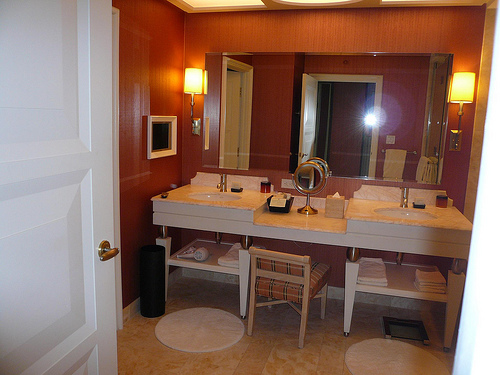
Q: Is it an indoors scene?
A: Yes, it is indoors.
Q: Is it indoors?
A: Yes, it is indoors.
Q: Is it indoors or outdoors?
A: It is indoors.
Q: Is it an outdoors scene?
A: No, it is indoors.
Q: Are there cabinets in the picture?
A: No, there are no cabinets.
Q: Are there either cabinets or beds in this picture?
A: No, there are no cabinets or beds.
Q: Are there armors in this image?
A: No, there are no armors.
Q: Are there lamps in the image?
A: Yes, there is a lamp.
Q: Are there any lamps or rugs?
A: Yes, there is a lamp.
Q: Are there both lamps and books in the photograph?
A: No, there is a lamp but no books.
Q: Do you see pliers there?
A: No, there are no pliers.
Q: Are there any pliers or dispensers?
A: No, there are no pliers or dispensers.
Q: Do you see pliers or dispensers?
A: No, there are no pliers or dispensers.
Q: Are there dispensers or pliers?
A: No, there are no pliers or dispensers.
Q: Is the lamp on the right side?
A: Yes, the lamp is on the right of the image.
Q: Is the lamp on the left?
A: No, the lamp is on the right of the image.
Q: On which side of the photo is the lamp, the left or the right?
A: The lamp is on the right of the image.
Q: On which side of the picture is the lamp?
A: The lamp is on the right of the image.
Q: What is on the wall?
A: The lamp is on the wall.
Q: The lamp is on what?
A: The lamp is on the wall.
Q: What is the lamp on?
A: The lamp is on the wall.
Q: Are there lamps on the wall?
A: Yes, there is a lamp on the wall.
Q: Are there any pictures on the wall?
A: No, there is a lamp on the wall.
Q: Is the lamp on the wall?
A: Yes, the lamp is on the wall.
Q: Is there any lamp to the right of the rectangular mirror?
A: Yes, there is a lamp to the right of the mirror.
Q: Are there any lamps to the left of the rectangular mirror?
A: No, the lamp is to the right of the mirror.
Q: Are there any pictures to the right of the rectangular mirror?
A: No, there is a lamp to the right of the mirror.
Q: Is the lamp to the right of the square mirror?
A: Yes, the lamp is to the right of the mirror.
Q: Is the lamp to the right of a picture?
A: No, the lamp is to the right of the mirror.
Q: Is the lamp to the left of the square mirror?
A: No, the lamp is to the right of the mirror.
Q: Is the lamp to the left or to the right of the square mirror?
A: The lamp is to the right of the mirror.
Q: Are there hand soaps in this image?
A: No, there are no hand soaps.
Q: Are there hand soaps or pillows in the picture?
A: No, there are no hand soaps or pillows.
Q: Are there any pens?
A: No, there are no pens.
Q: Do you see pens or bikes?
A: No, there are no pens or bikes.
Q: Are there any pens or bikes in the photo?
A: No, there are no pens or bikes.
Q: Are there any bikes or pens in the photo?
A: No, there are no pens or bikes.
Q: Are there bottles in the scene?
A: No, there are no bottles.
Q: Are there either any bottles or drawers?
A: No, there are no bottles or drawers.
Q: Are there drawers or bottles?
A: No, there are no bottles or drawers.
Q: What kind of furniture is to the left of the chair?
A: The piece of furniture is a shelf.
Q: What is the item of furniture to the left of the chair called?
A: The piece of furniture is a shelf.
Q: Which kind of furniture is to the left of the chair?
A: The piece of furniture is a shelf.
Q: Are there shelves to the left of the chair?
A: Yes, there is a shelf to the left of the chair.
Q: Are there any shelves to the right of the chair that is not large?
A: No, the shelf is to the left of the chair.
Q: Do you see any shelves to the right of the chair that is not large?
A: No, the shelf is to the left of the chair.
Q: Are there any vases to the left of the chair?
A: No, there is a shelf to the left of the chair.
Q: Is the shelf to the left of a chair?
A: Yes, the shelf is to the left of a chair.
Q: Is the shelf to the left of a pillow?
A: No, the shelf is to the left of a chair.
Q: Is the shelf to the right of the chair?
A: No, the shelf is to the left of the chair.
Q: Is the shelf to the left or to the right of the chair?
A: The shelf is to the left of the chair.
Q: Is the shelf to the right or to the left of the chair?
A: The shelf is to the left of the chair.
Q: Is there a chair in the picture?
A: Yes, there is a chair.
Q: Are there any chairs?
A: Yes, there is a chair.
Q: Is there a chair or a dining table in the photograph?
A: Yes, there is a chair.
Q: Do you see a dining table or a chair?
A: Yes, there is a chair.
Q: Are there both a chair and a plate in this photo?
A: No, there is a chair but no plates.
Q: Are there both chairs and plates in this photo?
A: No, there is a chair but no plates.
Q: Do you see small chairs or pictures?
A: Yes, there is a small chair.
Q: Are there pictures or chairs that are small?
A: Yes, the chair is small.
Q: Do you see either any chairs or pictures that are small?
A: Yes, the chair is small.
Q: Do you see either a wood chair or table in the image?
A: Yes, there is a wood chair.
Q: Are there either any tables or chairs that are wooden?
A: Yes, the chair is wooden.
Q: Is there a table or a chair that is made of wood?
A: Yes, the chair is made of wood.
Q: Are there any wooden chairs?
A: Yes, there is a wood chair.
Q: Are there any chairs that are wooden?
A: Yes, there is a chair that is wooden.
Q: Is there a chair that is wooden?
A: Yes, there is a chair that is wooden.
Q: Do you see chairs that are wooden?
A: Yes, there is a chair that is wooden.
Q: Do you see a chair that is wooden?
A: Yes, there is a chair that is wooden.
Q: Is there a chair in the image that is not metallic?
A: Yes, there is a wooden chair.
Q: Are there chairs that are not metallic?
A: Yes, there is a wooden chair.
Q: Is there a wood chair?
A: Yes, there is a chair that is made of wood.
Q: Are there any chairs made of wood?
A: Yes, there is a chair that is made of wood.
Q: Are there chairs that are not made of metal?
A: Yes, there is a chair that is made of wood.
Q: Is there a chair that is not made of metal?
A: Yes, there is a chair that is made of wood.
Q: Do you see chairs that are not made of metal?
A: Yes, there is a chair that is made of wood.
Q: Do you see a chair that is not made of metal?
A: Yes, there is a chair that is made of wood.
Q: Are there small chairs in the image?
A: Yes, there is a small chair.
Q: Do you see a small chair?
A: Yes, there is a small chair.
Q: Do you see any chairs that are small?
A: Yes, there is a chair that is small.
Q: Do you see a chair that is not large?
A: Yes, there is a small chair.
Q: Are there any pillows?
A: No, there are no pillows.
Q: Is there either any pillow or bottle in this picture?
A: No, there are no pillows or bottles.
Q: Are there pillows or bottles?
A: No, there are no pillows or bottles.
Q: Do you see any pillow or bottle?
A: No, there are no pillows or bottles.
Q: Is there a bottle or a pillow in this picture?
A: No, there are no pillows or bottles.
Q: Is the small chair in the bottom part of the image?
A: Yes, the chair is in the bottom of the image.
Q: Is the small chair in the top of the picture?
A: No, the chair is in the bottom of the image.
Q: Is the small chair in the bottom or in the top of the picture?
A: The chair is in the bottom of the image.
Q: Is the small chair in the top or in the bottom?
A: The chair is in the bottom of the image.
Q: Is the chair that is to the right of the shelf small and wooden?
A: Yes, the chair is small and wooden.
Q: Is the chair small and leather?
A: No, the chair is small but wooden.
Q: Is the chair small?
A: Yes, the chair is small.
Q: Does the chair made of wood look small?
A: Yes, the chair is small.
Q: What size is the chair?
A: The chair is small.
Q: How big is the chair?
A: The chair is small.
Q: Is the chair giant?
A: No, the chair is small.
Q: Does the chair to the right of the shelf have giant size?
A: No, the chair is small.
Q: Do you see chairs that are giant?
A: No, there is a chair but it is small.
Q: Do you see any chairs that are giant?
A: No, there is a chair but it is small.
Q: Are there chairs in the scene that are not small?
A: No, there is a chair but it is small.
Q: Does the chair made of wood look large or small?
A: The chair is small.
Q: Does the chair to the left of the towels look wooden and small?
A: Yes, the chair is wooden and small.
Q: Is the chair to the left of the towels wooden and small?
A: Yes, the chair is wooden and small.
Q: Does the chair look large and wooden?
A: No, the chair is wooden but small.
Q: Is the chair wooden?
A: Yes, the chair is wooden.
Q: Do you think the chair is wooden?
A: Yes, the chair is wooden.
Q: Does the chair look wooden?
A: Yes, the chair is wooden.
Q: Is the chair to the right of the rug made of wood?
A: Yes, the chair is made of wood.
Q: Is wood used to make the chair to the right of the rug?
A: Yes, the chair is made of wood.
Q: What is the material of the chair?
A: The chair is made of wood.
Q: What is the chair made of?
A: The chair is made of wood.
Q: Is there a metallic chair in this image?
A: No, there is a chair but it is wooden.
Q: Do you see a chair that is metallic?
A: No, there is a chair but it is wooden.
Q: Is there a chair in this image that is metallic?
A: No, there is a chair but it is wooden.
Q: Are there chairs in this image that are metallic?
A: No, there is a chair but it is wooden.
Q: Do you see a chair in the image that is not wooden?
A: No, there is a chair but it is wooden.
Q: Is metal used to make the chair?
A: No, the chair is made of wood.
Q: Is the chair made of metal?
A: No, the chair is made of wood.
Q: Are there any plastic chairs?
A: No, there is a chair but it is made of wood.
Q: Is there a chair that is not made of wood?
A: No, there is a chair but it is made of wood.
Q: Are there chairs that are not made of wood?
A: No, there is a chair but it is made of wood.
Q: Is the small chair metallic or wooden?
A: The chair is wooden.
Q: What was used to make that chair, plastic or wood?
A: The chair is made of wood.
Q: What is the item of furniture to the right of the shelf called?
A: The piece of furniture is a chair.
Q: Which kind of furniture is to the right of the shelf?
A: The piece of furniture is a chair.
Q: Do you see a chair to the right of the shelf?
A: Yes, there is a chair to the right of the shelf.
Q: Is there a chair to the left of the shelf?
A: No, the chair is to the right of the shelf.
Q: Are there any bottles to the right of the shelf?
A: No, there is a chair to the right of the shelf.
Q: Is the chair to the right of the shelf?
A: Yes, the chair is to the right of the shelf.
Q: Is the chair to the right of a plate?
A: No, the chair is to the right of the shelf.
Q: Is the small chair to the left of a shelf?
A: No, the chair is to the right of a shelf.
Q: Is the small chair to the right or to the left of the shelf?
A: The chair is to the right of the shelf.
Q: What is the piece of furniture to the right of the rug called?
A: The piece of furniture is a chair.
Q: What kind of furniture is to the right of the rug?
A: The piece of furniture is a chair.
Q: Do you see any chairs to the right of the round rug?
A: Yes, there is a chair to the right of the rug.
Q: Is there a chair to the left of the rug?
A: No, the chair is to the right of the rug.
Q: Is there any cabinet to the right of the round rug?
A: No, there is a chair to the right of the rug.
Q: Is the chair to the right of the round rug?
A: Yes, the chair is to the right of the rug.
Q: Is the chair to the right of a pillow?
A: No, the chair is to the right of the rug.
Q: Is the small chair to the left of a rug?
A: No, the chair is to the right of a rug.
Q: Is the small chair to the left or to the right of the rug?
A: The chair is to the right of the rug.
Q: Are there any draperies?
A: No, there are no draperies.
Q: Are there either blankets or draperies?
A: No, there are no draperies or blankets.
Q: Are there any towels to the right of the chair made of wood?
A: Yes, there are towels to the right of the chair.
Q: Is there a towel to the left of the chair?
A: No, the towels are to the right of the chair.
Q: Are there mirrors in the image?
A: Yes, there is a mirror.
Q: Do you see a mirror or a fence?
A: Yes, there is a mirror.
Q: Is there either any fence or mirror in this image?
A: Yes, there is a mirror.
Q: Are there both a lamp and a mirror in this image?
A: Yes, there are both a mirror and a lamp.